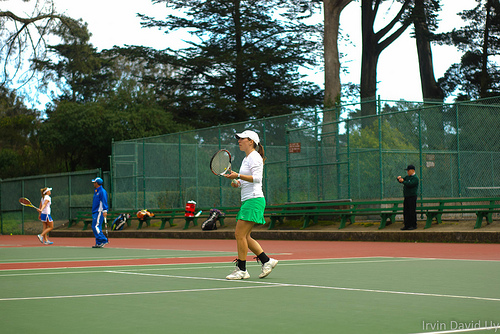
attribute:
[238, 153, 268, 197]
jersey — White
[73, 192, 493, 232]
bench — green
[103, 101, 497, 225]
fence — metal, steel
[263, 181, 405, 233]
bench — green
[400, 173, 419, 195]
sweatshirt — green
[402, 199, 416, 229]
pants — black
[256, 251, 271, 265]
sock — black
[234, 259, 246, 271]
sock — black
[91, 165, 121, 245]
man — white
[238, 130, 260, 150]
cap — white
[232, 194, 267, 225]
skirt — green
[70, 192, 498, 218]
bench — green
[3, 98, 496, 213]
fence — green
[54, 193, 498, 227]
bench — green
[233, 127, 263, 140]
cap — white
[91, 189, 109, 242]
warm-up suit — blue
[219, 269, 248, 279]
sock — black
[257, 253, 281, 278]
sock — black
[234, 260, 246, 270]
sock — black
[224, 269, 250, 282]
shoe — white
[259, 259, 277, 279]
shoe — white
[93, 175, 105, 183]
hat — blue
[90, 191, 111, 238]
clothes — blue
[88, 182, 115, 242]
clothes — blue